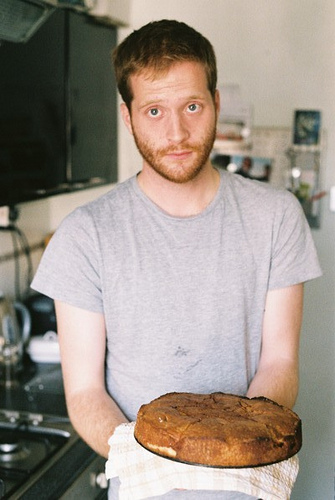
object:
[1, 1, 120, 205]
cabinet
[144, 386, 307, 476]
cake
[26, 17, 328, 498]
man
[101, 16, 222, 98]
hair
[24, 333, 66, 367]
butter container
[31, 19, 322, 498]
person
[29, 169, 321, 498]
t-shirt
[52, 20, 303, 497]
man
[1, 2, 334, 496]
kitchen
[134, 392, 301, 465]
cake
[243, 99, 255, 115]
ground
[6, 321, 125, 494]
stove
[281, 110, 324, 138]
picture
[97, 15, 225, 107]
hair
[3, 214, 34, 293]
wires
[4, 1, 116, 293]
wall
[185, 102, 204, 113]
eye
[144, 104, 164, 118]
eye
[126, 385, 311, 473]
cake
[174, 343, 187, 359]
stain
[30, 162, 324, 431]
t shirt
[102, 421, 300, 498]
towel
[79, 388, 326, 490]
towel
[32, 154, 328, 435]
shirt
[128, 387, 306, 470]
pastry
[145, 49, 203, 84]
wall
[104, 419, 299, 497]
cloth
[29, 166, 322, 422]
shirt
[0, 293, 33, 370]
blender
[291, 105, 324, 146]
picture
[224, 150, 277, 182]
picture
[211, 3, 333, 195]
wall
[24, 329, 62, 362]
container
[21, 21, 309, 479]
man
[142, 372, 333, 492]
bread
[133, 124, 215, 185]
beard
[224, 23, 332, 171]
wall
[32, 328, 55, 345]
lid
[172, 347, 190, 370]
stain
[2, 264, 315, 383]
counter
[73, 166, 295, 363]
man